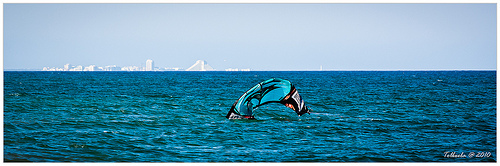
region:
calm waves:
[5, 104, 222, 163]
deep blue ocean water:
[6, 72, 208, 157]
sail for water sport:
[225, 78, 310, 119]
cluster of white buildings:
[41, 55, 250, 72]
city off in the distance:
[44, 56, 253, 71]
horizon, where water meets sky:
[360, 65, 499, 72]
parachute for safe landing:
[226, 78, 314, 118]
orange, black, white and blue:
[225, 78, 317, 120]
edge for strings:
[296, 112, 316, 119]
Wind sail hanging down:
[225, 75, 310, 125]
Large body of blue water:
[1, 68, 491, 158]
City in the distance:
[39, 57, 253, 70]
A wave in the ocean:
[66, 129, 159, 156]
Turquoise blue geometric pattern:
[233, 75, 288, 117]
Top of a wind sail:
[294, 106, 311, 117]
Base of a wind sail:
[226, 106, 253, 121]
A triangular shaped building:
[188, 59, 214, 71]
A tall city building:
[144, 58, 154, 70]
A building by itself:
[318, 64, 324, 69]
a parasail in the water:
[201, 58, 323, 153]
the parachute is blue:
[206, 55, 339, 145]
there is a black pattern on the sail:
[204, 64, 344, 159]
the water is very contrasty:
[11, 69, 498, 164]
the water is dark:
[3, 72, 498, 162]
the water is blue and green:
[4, 72, 497, 160]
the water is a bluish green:
[1, 69, 496, 164]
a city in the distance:
[26, 50, 252, 76]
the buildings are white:
[38, 46, 223, 78]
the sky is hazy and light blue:
[3, 4, 495, 87]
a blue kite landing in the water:
[228, 78, 308, 121]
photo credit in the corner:
[443, 149, 492, 157]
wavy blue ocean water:
[2, 70, 497, 164]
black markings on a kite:
[227, 79, 309, 120]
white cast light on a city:
[42, 61, 250, 71]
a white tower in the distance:
[318, 64, 324, 71]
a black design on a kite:
[250, 87, 272, 102]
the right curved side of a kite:
[287, 84, 306, 116]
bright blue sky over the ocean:
[2, 1, 498, 71]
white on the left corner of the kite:
[229, 111, 240, 120]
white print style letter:
[441, 149, 448, 159]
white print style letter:
[445, 152, 449, 158]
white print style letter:
[448, 150, 452, 158]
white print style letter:
[453, 153, 457, 158]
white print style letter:
[459, 150, 462, 160]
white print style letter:
[461, 152, 469, 157]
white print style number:
[473, 149, 480, 159]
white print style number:
[478, 150, 483, 158]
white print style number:
[483, 149, 487, 161]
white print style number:
[484, 147, 491, 161]